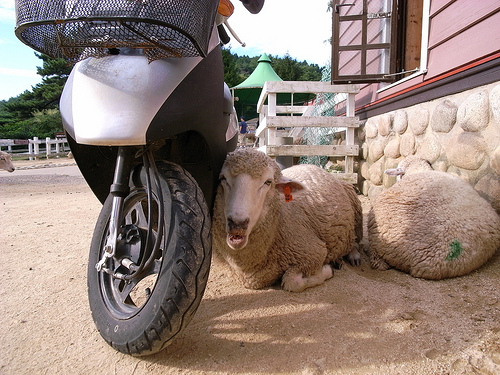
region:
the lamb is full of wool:
[213, 148, 361, 297]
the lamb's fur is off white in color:
[213, 145, 365, 292]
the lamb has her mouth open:
[216, 149, 305, 259]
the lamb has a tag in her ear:
[283, 184, 292, 203]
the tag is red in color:
[283, 185, 293, 200]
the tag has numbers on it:
[283, 191, 293, 203]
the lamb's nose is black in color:
[226, 212, 250, 231]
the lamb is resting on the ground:
[213, 148, 365, 292]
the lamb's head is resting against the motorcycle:
[218, 147, 297, 253]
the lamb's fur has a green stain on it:
[445, 236, 467, 265]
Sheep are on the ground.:
[204, 137, 498, 307]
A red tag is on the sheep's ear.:
[270, 175, 302, 205]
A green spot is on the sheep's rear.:
[429, 236, 474, 271]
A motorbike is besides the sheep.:
[12, 0, 277, 362]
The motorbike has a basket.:
[7, 0, 242, 74]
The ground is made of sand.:
[0, 280, 488, 372]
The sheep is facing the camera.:
[210, 133, 310, 265]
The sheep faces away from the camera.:
[368, 150, 498, 282]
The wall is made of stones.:
[354, 80, 497, 250]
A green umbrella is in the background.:
[220, 47, 310, 105]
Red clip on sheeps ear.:
[247, 154, 326, 233]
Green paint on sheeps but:
[347, 223, 487, 348]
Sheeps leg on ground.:
[245, 255, 345, 318]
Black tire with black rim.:
[83, 168, 190, 338]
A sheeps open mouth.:
[213, 205, 258, 256]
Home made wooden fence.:
[227, 54, 363, 238]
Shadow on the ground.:
[130, 274, 387, 370]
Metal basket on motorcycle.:
[10, 1, 285, 93]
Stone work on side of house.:
[358, 85, 485, 171]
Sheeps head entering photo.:
[1, 144, 46, 176]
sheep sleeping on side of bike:
[194, 141, 364, 305]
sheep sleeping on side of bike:
[94, 106, 406, 291]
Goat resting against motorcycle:
[202, 121, 357, 298]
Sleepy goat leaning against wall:
[368, 135, 498, 286]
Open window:
[322, 0, 458, 99]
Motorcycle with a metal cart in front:
[18, 6, 210, 373]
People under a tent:
[237, 55, 338, 150]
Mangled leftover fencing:
[298, 51, 339, 168]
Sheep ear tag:
[258, 163, 310, 216]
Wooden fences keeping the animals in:
[0, 122, 56, 188]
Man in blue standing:
[230, 105, 260, 152]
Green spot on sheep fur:
[424, 225, 476, 275]